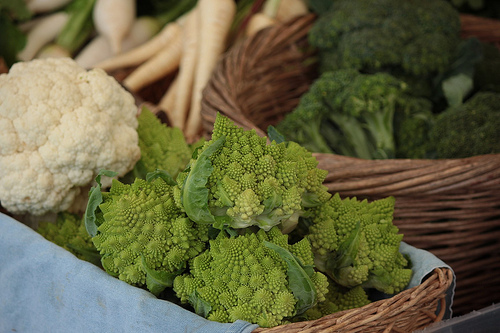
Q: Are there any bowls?
A: No, there are no bowls.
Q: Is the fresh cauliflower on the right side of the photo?
A: No, the cauliflower is on the left of the image.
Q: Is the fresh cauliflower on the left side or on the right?
A: The cauliflower is on the left of the image.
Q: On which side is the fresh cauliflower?
A: The cauliflower is on the left of the image.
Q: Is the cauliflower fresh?
A: Yes, the cauliflower is fresh.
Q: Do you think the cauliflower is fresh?
A: Yes, the cauliflower is fresh.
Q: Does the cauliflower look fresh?
A: Yes, the cauliflower is fresh.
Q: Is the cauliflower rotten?
A: No, the cauliflower is fresh.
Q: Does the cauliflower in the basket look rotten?
A: No, the cauliflower is fresh.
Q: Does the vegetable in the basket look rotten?
A: No, the cauliflower is fresh.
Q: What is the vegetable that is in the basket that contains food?
A: The vegetable is cauliflower.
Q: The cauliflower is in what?
A: The cauliflower is in the basket.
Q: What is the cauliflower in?
A: The cauliflower is in the basket.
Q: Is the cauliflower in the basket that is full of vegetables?
A: Yes, the cauliflower is in the basket.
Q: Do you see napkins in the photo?
A: No, there are no napkins.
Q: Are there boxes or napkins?
A: No, there are no napkins or boxes.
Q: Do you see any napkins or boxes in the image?
A: No, there are no napkins or boxes.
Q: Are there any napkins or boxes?
A: No, there are no napkins or boxes.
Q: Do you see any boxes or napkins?
A: No, there are no napkins or boxes.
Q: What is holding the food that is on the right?
A: The basket is holding the food.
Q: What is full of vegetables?
A: The basket is full of vegetables.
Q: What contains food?
A: The basket contains food.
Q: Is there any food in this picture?
A: Yes, there is food.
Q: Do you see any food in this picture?
A: Yes, there is food.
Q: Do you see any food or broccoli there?
A: Yes, there is food.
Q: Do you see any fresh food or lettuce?
A: Yes, there is fresh food.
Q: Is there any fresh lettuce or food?
A: Yes, there is fresh food.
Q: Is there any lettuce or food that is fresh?
A: Yes, the food is fresh.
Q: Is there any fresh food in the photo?
A: Yes, there is fresh food.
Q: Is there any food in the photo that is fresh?
A: Yes, there is food that is fresh.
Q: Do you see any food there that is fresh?
A: Yes, there is food that is fresh.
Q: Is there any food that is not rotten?
A: Yes, there is fresh food.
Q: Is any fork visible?
A: No, there are no forks.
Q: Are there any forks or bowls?
A: No, there are no forks or bowls.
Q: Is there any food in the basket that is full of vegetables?
A: Yes, there is food in the basket.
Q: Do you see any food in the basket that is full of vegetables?
A: Yes, there is food in the basket.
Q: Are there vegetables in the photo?
A: Yes, there are vegetables.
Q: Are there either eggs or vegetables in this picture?
A: Yes, there are vegetables.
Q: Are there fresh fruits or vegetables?
A: Yes, there are fresh vegetables.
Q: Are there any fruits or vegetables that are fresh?
A: Yes, the vegetables are fresh.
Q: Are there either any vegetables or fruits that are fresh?
A: Yes, the vegetables are fresh.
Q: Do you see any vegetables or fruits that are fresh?
A: Yes, the vegetables are fresh.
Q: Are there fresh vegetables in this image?
A: Yes, there are fresh vegetables.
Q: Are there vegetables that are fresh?
A: Yes, there are vegetables that are fresh.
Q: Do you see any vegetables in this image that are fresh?
A: Yes, there are vegetables that are fresh.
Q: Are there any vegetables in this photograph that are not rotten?
A: Yes, there are fresh vegetables.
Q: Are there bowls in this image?
A: No, there are no bowls.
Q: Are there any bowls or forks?
A: No, there are no bowls or forks.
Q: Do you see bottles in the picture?
A: No, there are no bottles.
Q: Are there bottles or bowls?
A: No, there are no bottles or bowls.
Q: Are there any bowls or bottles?
A: No, there are no bottles or bowls.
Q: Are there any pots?
A: No, there are no pots.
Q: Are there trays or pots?
A: No, there are no pots or trays.